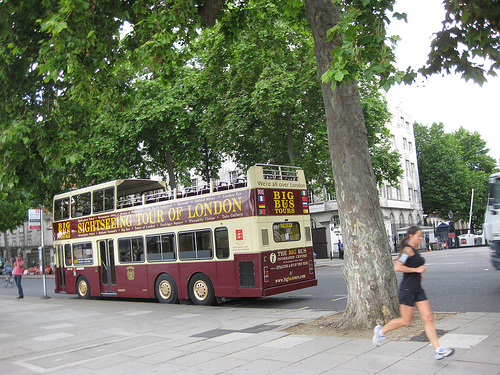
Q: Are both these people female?
A: Yes, all the people are female.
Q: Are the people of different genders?
A: No, all the people are female.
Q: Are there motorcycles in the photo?
A: No, there are no motorcycles.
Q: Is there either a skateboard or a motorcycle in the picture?
A: No, there are no motorcycles or skateboards.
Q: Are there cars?
A: No, there are no cars.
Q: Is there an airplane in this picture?
A: No, there are no airplanes.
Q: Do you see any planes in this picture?
A: No, there are no planes.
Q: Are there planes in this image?
A: No, there are no planes.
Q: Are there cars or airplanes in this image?
A: No, there are no airplanes or cars.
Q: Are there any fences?
A: No, there are no fences.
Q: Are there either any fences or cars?
A: No, there are no fences or cars.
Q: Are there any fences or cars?
A: No, there are no fences or cars.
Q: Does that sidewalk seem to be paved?
A: Yes, the sidewalk is paved.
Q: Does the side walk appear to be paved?
A: Yes, the side walk is paved.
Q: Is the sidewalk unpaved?
A: No, the sidewalk is paved.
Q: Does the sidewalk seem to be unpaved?
A: No, the sidewalk is paved.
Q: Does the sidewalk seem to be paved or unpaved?
A: The sidewalk is paved.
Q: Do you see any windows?
A: Yes, there are windows.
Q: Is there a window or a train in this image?
A: Yes, there are windows.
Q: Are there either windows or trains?
A: Yes, there are windows.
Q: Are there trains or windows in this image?
A: Yes, there are windows.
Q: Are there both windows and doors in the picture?
A: Yes, there are both windows and a door.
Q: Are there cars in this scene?
A: No, there are no cars.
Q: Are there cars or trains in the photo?
A: No, there are no cars or trains.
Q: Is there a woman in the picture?
A: Yes, there is a woman.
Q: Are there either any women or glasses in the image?
A: Yes, there is a woman.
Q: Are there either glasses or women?
A: Yes, there is a woman.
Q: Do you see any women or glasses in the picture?
A: Yes, there is a woman.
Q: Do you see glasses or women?
A: Yes, there is a woman.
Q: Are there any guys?
A: No, there are no guys.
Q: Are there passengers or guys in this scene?
A: No, there are no guys or passengers.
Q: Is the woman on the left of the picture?
A: Yes, the woman is on the left of the image.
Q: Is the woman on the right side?
A: No, the woman is on the left of the image.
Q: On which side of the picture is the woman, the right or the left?
A: The woman is on the left of the image.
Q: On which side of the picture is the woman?
A: The woman is on the left of the image.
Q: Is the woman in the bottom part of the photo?
A: Yes, the woman is in the bottom of the image.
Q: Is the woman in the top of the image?
A: No, the woman is in the bottom of the image.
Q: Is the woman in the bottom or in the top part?
A: The woman is in the bottom of the image.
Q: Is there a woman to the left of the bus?
A: Yes, there is a woman to the left of the bus.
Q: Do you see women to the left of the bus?
A: Yes, there is a woman to the left of the bus.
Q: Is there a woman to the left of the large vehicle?
A: Yes, there is a woman to the left of the bus.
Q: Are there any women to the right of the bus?
A: No, the woman is to the left of the bus.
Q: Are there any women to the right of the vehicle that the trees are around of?
A: No, the woman is to the left of the bus.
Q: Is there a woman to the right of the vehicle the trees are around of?
A: No, the woman is to the left of the bus.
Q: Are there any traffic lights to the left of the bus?
A: No, there is a woman to the left of the bus.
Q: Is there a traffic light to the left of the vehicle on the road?
A: No, there is a woman to the left of the bus.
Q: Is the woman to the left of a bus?
A: Yes, the woman is to the left of a bus.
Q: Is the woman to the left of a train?
A: No, the woman is to the left of a bus.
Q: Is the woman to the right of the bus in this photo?
A: No, the woman is to the left of the bus.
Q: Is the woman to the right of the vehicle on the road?
A: No, the woman is to the left of the bus.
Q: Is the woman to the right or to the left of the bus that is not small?
A: The woman is to the left of the bus.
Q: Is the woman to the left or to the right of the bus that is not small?
A: The woman is to the left of the bus.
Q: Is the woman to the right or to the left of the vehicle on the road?
A: The woman is to the left of the bus.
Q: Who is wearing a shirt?
A: The woman is wearing a shirt.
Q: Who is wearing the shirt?
A: The woman is wearing a shirt.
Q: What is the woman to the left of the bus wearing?
A: The woman is wearing a shirt.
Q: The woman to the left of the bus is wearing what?
A: The woman is wearing a shirt.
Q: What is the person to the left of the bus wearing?
A: The woman is wearing a shirt.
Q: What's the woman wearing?
A: The woman is wearing a shirt.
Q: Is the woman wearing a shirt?
A: Yes, the woman is wearing a shirt.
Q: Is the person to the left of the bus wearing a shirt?
A: Yes, the woman is wearing a shirt.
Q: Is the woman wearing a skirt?
A: No, the woman is wearing a shirt.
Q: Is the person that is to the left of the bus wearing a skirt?
A: No, the woman is wearing a shirt.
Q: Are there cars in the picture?
A: No, there are no cars.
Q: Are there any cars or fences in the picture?
A: No, there are no cars or fences.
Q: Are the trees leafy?
A: Yes, the trees are leafy.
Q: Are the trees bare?
A: No, the trees are leafy.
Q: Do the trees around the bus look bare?
A: No, the trees are leafy.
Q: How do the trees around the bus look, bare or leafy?
A: The trees are leafy.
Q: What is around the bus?
A: The trees are around the bus.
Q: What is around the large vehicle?
A: The trees are around the bus.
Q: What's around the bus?
A: The trees are around the bus.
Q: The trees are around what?
A: The trees are around the bus.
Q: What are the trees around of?
A: The trees are around the bus.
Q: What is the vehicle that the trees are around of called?
A: The vehicle is a bus.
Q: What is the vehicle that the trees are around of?
A: The vehicle is a bus.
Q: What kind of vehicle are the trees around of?
A: The trees are around the bus.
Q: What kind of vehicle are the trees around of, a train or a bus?
A: The trees are around a bus.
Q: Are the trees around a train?
A: No, the trees are around a bus.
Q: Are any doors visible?
A: Yes, there is a door.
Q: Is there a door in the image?
A: Yes, there is a door.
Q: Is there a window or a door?
A: Yes, there is a door.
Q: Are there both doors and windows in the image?
A: Yes, there are both a door and a window.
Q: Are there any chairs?
A: No, there are no chairs.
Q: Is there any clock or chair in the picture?
A: No, there are no chairs or clocks.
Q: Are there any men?
A: No, there are no men.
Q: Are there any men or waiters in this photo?
A: No, there are no men or waiters.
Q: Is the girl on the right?
A: Yes, the girl is on the right of the image.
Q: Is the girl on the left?
A: No, the girl is on the right of the image.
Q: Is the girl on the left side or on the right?
A: The girl is on the right of the image.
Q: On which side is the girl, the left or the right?
A: The girl is on the right of the image.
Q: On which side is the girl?
A: The girl is on the right of the image.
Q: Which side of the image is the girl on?
A: The girl is on the right of the image.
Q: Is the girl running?
A: Yes, the girl is running.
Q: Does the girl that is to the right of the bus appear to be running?
A: Yes, the girl is running.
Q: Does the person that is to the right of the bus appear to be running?
A: Yes, the girl is running.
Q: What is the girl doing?
A: The girl is running.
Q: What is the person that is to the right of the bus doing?
A: The girl is running.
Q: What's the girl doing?
A: The girl is running.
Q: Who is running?
A: The girl is running.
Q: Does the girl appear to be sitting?
A: No, the girl is running.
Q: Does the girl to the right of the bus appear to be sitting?
A: No, the girl is running.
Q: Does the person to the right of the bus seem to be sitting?
A: No, the girl is running.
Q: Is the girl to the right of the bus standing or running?
A: The girl is running.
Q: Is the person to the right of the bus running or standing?
A: The girl is running.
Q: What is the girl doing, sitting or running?
A: The girl is running.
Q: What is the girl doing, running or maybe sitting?
A: The girl is running.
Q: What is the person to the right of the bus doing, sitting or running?
A: The girl is running.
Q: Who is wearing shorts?
A: The girl is wearing shorts.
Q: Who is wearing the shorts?
A: The girl is wearing shorts.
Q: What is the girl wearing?
A: The girl is wearing shorts.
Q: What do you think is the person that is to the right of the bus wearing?
A: The girl is wearing shorts.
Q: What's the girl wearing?
A: The girl is wearing shorts.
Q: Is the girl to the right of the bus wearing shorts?
A: Yes, the girl is wearing shorts.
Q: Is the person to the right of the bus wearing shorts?
A: Yes, the girl is wearing shorts.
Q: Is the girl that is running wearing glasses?
A: No, the girl is wearing shorts.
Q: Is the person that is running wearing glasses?
A: No, the girl is wearing shorts.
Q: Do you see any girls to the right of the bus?
A: Yes, there is a girl to the right of the bus.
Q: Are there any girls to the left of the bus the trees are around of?
A: No, the girl is to the right of the bus.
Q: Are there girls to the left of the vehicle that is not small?
A: No, the girl is to the right of the bus.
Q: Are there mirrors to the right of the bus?
A: No, there is a girl to the right of the bus.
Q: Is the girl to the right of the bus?
A: Yes, the girl is to the right of the bus.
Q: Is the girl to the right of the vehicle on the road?
A: Yes, the girl is to the right of the bus.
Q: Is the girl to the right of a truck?
A: No, the girl is to the right of the bus.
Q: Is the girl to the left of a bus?
A: No, the girl is to the right of a bus.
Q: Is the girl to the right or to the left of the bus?
A: The girl is to the right of the bus.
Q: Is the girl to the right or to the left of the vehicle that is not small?
A: The girl is to the right of the bus.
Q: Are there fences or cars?
A: No, there are no fences or cars.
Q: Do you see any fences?
A: No, there are no fences.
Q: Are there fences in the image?
A: No, there are no fences.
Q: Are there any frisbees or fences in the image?
A: No, there are no fences or frisbees.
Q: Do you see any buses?
A: Yes, there is a bus.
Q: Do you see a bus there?
A: Yes, there is a bus.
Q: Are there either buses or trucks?
A: Yes, there is a bus.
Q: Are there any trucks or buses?
A: Yes, there is a bus.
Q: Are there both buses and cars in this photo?
A: No, there is a bus but no cars.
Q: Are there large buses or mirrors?
A: Yes, there is a large bus.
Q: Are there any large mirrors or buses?
A: Yes, there is a large bus.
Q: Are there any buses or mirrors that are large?
A: Yes, the bus is large.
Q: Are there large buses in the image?
A: Yes, there is a large bus.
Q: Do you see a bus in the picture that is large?
A: Yes, there is a bus that is large.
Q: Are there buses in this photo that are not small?
A: Yes, there is a large bus.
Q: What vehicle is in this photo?
A: The vehicle is a bus.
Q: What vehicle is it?
A: The vehicle is a bus.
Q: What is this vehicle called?
A: This is a bus.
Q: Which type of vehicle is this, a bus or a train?
A: This is a bus.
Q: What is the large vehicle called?
A: The vehicle is a bus.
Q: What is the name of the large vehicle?
A: The vehicle is a bus.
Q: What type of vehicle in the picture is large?
A: The vehicle is a bus.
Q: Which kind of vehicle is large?
A: The vehicle is a bus.